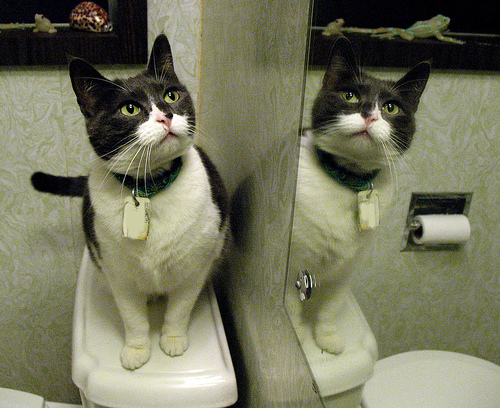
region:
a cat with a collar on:
[106, 139, 228, 239]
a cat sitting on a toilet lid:
[56, 67, 247, 387]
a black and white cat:
[88, 5, 242, 331]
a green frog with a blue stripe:
[354, 0, 474, 61]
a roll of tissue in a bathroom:
[398, 175, 496, 262]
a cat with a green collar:
[113, 139, 213, 227]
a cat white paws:
[100, 317, 226, 378]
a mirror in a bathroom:
[274, 30, 486, 310]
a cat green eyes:
[106, 70, 206, 127]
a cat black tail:
[29, 144, 101, 214]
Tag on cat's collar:
[120, 193, 150, 240]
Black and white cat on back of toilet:
[30, 31, 229, 370]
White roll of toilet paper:
[416, 214, 473, 245]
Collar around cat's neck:
[110, 155, 187, 197]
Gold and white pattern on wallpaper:
[3, 73, 60, 170]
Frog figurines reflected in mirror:
[322, 7, 466, 47]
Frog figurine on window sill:
[30, 12, 55, 32]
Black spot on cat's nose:
[156, 111, 172, 125]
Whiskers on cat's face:
[78, 125, 161, 217]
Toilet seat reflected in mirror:
[363, 333, 498, 404]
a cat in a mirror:
[22, 27, 496, 371]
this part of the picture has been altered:
[26, 1, 478, 46]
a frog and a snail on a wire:
[25, 4, 118, 39]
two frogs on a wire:
[320, 8, 475, 52]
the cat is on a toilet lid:
[23, 39, 255, 394]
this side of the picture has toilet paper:
[403, 182, 488, 269]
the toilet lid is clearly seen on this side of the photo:
[349, 311, 497, 403]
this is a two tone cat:
[56, 45, 241, 376]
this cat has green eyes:
[109, 80, 190, 115]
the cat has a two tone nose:
[340, 109, 387, 152]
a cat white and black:
[10, 19, 239, 381]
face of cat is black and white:
[110, 80, 196, 152]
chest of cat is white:
[95, 187, 202, 301]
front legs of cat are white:
[110, 282, 204, 374]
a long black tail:
[24, 161, 90, 209]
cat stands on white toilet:
[21, 28, 251, 405]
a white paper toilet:
[406, 201, 476, 259]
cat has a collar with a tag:
[57, 30, 212, 246]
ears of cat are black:
[53, 24, 198, 90]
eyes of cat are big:
[106, 83, 187, 121]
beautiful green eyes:
[116, 100, 141, 118]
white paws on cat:
[155, 331, 191, 355]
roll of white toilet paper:
[405, 209, 480, 255]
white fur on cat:
[170, 221, 213, 274]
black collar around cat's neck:
[98, 157, 203, 199]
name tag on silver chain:
[116, 191, 171, 235]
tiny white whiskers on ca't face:
[375, 132, 424, 197]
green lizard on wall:
[355, 9, 461, 47]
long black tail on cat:
[24, 160, 122, 202]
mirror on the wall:
[285, 67, 446, 239]